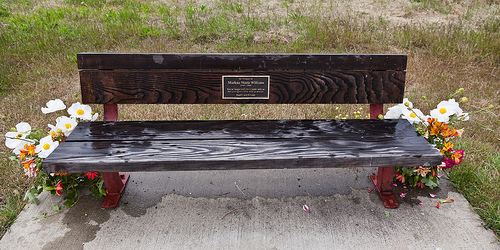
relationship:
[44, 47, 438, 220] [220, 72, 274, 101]
bench has plaque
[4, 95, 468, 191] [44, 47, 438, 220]
flowers besides bench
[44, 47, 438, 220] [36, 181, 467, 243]
bench bolted in concrete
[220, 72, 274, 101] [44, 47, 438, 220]
plaque mounted on bench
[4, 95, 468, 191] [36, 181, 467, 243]
flowers are on top of concrete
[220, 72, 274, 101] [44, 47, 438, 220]
plaque mounted to bench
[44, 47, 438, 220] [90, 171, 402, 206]
bench has metal legs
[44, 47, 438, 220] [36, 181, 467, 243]
bench on concrete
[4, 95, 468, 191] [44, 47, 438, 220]
flowers on both sides of bench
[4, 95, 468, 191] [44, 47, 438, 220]
flowers beside bench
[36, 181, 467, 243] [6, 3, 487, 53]
concrete surrounded by grass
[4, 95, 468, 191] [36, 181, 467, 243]
flowers on concrete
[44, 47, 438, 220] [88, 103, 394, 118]
bench has gap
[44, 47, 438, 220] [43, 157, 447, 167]
bench has edge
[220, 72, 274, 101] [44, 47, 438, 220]
plaque on bench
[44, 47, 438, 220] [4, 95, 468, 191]
bench besides flowers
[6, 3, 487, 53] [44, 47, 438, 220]
grass near bench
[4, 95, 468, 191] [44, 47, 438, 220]
flowers near bench